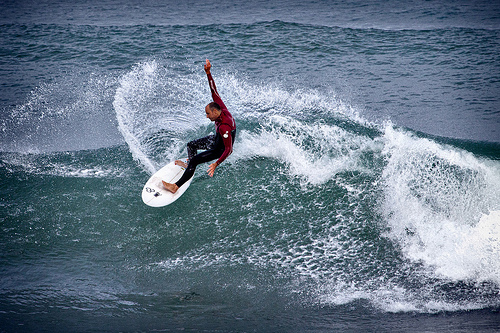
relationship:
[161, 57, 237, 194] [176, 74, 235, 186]
man wearing wet suit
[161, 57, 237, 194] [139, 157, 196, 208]
man balancing on surfboard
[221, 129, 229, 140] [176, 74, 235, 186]
logo on wet suit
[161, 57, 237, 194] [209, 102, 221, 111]
man has hair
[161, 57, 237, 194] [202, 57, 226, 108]
man has arm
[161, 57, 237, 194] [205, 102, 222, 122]
man has head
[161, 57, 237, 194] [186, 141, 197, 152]
man has knee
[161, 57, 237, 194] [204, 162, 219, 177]
man has hand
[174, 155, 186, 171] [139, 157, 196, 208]
foot on surfboard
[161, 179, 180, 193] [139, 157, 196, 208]
foot on surfboard